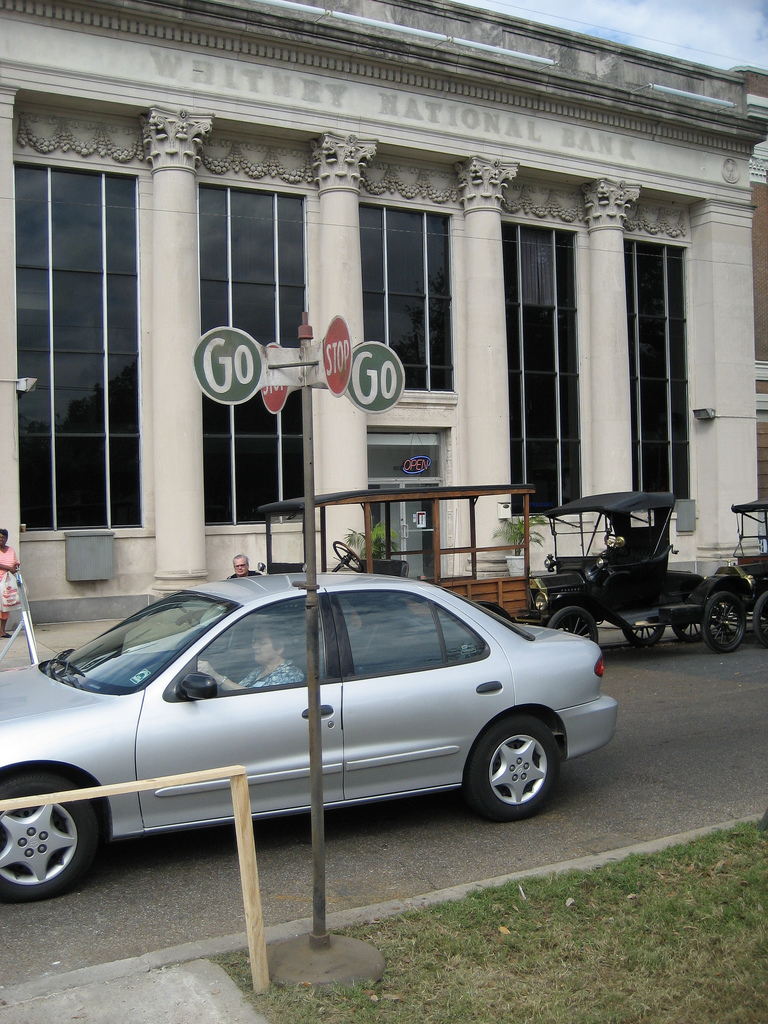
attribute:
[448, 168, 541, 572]
column — stone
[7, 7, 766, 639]
building — stone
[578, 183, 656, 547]
column — stone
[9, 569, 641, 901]
car — gray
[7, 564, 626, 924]
car — gray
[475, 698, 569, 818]
wheel — back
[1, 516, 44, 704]
bag — white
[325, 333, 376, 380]
street sign — red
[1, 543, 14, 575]
dress — pink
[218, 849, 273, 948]
fence — small and wooden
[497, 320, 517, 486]
frame — white